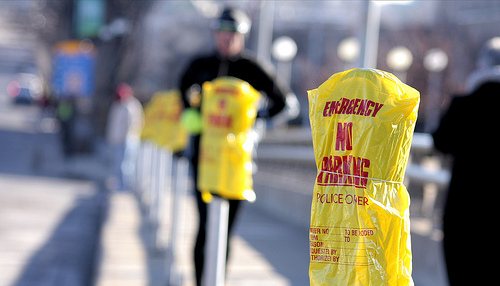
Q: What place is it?
A: It is a sidewalk.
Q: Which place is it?
A: It is a sidewalk.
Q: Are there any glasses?
A: No, there are no glasses.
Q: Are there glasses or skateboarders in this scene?
A: No, there are no glasses or skateboarders.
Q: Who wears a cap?
A: The man wears a cap.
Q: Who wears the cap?
A: The man wears a cap.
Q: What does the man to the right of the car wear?
A: The man wears a cap.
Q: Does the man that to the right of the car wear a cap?
A: Yes, the man wears a cap.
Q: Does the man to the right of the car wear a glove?
A: No, the man wears a cap.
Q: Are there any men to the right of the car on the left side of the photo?
A: Yes, there is a man to the right of the car.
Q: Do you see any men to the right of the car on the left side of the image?
A: Yes, there is a man to the right of the car.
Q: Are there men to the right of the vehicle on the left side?
A: Yes, there is a man to the right of the car.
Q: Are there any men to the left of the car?
A: No, the man is to the right of the car.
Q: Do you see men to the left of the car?
A: No, the man is to the right of the car.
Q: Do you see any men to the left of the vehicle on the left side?
A: No, the man is to the right of the car.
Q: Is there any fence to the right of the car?
A: No, there is a man to the right of the car.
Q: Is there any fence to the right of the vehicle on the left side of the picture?
A: No, there is a man to the right of the car.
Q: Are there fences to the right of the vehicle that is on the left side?
A: No, there is a man to the right of the car.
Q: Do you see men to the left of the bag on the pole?
A: Yes, there is a man to the left of the bag.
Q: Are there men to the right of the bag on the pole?
A: No, the man is to the left of the bag.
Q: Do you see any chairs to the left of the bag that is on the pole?
A: No, there is a man to the left of the bag.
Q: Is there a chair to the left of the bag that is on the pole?
A: No, there is a man to the left of the bag.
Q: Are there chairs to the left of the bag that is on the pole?
A: No, there is a man to the left of the bag.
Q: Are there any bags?
A: Yes, there is a bag.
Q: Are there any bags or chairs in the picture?
A: Yes, there is a bag.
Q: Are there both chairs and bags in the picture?
A: No, there is a bag but no chairs.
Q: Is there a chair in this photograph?
A: No, there are no chairs.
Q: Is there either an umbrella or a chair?
A: No, there are no chairs or umbrellas.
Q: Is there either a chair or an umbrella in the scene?
A: No, there are no chairs or umbrellas.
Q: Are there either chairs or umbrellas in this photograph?
A: No, there are no chairs or umbrellas.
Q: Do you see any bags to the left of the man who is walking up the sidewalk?
A: Yes, there is a bag to the left of the man.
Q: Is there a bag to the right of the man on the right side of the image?
A: No, the bag is to the left of the man.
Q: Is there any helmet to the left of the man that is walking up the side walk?
A: No, there is a bag to the left of the man.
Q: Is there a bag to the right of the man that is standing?
A: Yes, there is a bag to the right of the man.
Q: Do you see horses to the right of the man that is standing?
A: No, there is a bag to the right of the man.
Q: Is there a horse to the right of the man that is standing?
A: No, there is a bag to the right of the man.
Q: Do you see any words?
A: Yes, there are words.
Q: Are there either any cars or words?
A: Yes, there are words.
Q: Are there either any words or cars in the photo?
A: Yes, there are words.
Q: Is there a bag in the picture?
A: Yes, there is a bag.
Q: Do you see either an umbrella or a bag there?
A: Yes, there is a bag.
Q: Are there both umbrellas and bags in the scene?
A: No, there is a bag but no umbrellas.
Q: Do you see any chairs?
A: No, there are no chairs.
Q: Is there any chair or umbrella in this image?
A: No, there are no chairs or umbrellas.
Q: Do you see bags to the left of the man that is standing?
A: Yes, there is a bag to the left of the man.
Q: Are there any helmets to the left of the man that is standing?
A: No, there is a bag to the left of the man.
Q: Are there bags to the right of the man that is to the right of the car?
A: Yes, there is a bag to the right of the man.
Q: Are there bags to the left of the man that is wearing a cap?
A: No, the bag is to the right of the man.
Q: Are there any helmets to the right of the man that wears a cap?
A: No, there is a bag to the right of the man.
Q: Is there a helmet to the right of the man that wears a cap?
A: No, there is a bag to the right of the man.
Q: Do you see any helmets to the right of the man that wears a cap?
A: No, there is a bag to the right of the man.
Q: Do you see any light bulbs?
A: No, there are no light bulbs.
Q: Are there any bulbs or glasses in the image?
A: No, there are no bulbs or glasses.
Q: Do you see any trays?
A: No, there are no trays.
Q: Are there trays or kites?
A: No, there are no trays or kites.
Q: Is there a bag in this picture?
A: Yes, there is a bag.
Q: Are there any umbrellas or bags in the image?
A: Yes, there is a bag.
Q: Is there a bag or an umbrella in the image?
A: Yes, there is a bag.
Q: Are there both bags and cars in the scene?
A: Yes, there are both a bag and a car.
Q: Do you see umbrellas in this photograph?
A: No, there are no umbrellas.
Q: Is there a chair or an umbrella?
A: No, there are no umbrellas or chairs.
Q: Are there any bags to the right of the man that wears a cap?
A: Yes, there is a bag to the right of the man.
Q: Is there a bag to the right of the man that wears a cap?
A: Yes, there is a bag to the right of the man.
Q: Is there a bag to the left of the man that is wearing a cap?
A: No, the bag is to the right of the man.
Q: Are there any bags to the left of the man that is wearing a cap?
A: No, the bag is to the right of the man.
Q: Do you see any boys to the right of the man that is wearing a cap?
A: No, there is a bag to the right of the man.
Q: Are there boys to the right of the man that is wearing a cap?
A: No, there is a bag to the right of the man.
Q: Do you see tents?
A: No, there are no tents.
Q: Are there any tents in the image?
A: No, there are no tents.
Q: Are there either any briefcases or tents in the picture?
A: No, there are no tents or briefcases.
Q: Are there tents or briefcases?
A: No, there are no tents or briefcases.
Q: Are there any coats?
A: Yes, there is a coat.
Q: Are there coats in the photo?
A: Yes, there is a coat.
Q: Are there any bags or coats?
A: Yes, there is a coat.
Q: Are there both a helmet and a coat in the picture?
A: No, there is a coat but no helmets.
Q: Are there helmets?
A: No, there are no helmets.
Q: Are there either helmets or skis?
A: No, there are no helmets or skis.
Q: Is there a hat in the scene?
A: Yes, there is a hat.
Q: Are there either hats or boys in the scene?
A: Yes, there is a hat.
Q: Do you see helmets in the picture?
A: No, there are no helmets.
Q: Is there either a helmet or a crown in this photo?
A: No, there are no helmets or crowns.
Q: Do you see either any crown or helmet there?
A: No, there are no helmets or crowns.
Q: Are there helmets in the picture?
A: No, there are no helmets.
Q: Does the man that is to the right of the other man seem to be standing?
A: Yes, the man is standing.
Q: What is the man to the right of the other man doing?
A: The man is standing.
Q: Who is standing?
A: The man is standing.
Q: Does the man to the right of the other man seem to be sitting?
A: No, the man is standing.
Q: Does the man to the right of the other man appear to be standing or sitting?
A: The man is standing.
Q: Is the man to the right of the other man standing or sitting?
A: The man is standing.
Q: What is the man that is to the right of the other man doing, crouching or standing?
A: The man is standing.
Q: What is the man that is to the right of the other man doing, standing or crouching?
A: The man is standing.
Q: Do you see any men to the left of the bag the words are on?
A: Yes, there is a man to the left of the bag.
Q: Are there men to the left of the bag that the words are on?
A: Yes, there is a man to the left of the bag.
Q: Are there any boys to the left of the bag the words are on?
A: No, there is a man to the left of the bag.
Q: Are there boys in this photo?
A: No, there are no boys.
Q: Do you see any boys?
A: No, there are no boys.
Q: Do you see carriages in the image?
A: No, there are no carriages.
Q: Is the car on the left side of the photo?
A: Yes, the car is on the left of the image.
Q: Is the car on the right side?
A: No, the car is on the left of the image.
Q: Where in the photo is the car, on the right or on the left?
A: The car is on the left of the image.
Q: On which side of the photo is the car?
A: The car is on the left of the image.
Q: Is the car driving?
A: Yes, the car is driving.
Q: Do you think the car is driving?
A: Yes, the car is driving.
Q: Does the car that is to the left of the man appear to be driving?
A: Yes, the car is driving.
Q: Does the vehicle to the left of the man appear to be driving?
A: Yes, the car is driving.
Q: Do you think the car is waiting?
A: No, the car is driving.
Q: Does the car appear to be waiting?
A: No, the car is driving.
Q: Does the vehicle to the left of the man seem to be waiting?
A: No, the car is driving.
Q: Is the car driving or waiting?
A: The car is driving.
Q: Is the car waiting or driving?
A: The car is driving.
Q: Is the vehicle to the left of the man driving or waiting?
A: The car is driving.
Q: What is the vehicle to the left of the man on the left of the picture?
A: The vehicle is a car.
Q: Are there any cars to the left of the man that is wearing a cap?
A: Yes, there is a car to the left of the man.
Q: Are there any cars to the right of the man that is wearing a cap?
A: No, the car is to the left of the man.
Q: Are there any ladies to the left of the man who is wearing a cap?
A: No, there is a car to the left of the man.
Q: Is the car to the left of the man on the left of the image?
A: Yes, the car is to the left of the man.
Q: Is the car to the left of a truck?
A: No, the car is to the left of the man.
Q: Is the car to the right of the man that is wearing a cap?
A: No, the car is to the left of the man.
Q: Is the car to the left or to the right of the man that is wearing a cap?
A: The car is to the left of the man.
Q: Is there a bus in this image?
A: No, there are no buses.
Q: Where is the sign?
A: The sign is on the road.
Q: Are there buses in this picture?
A: No, there are no buses.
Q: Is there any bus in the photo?
A: No, there are no buses.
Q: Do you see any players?
A: No, there are no players.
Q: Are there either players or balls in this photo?
A: No, there are no players or balls.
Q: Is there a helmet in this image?
A: No, there are no helmets.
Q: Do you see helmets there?
A: No, there are no helmets.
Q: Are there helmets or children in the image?
A: No, there are no helmets or children.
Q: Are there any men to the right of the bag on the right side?
A: Yes, there is a man to the right of the bag.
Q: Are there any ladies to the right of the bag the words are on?
A: No, there is a man to the right of the bag.